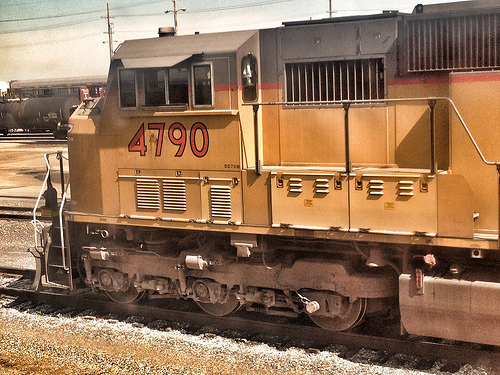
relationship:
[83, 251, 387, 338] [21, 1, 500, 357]
wheels of train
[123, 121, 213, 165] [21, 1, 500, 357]
number across train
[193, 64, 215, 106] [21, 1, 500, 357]
window of train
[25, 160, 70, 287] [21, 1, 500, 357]
stairs of train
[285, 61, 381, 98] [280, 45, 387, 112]
railing on window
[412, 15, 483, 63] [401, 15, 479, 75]
railing on window